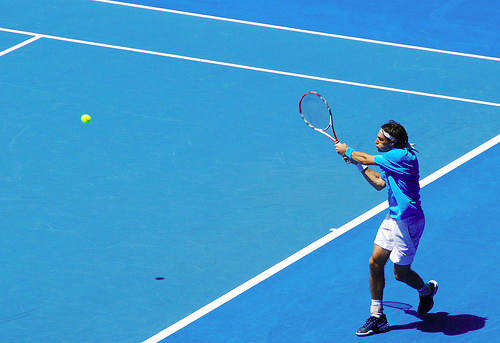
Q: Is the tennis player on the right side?
A: Yes, the player is on the right of the image.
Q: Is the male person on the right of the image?
A: Yes, the player is on the right of the image.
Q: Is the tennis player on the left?
A: No, the player is on the right of the image.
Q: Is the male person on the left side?
A: No, the player is on the right of the image.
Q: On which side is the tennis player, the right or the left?
A: The player is on the right of the image.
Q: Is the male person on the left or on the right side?
A: The player is on the right of the image.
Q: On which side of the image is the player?
A: The player is on the right of the image.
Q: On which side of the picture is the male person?
A: The player is on the right of the image.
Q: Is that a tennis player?
A: Yes, that is a tennis player.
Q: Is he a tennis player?
A: Yes, that is a tennis player.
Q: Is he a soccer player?
A: No, that is a tennis player.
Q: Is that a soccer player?
A: No, that is a tennis player.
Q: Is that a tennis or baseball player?
A: That is a tennis player.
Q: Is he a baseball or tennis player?
A: That is a tennis player.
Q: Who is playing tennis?
A: The player is playing tennis.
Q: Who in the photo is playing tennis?
A: The player is playing tennis.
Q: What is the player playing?
A: The player is playing tennis.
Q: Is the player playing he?
A: Yes, the player is playing tennis.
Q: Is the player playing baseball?
A: No, the player is playing tennis.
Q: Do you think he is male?
A: Yes, the player is male.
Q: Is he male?
A: Yes, the player is male.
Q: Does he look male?
A: Yes, the player is male.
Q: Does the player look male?
A: Yes, the player is male.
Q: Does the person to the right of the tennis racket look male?
A: Yes, the player is male.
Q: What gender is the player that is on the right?
A: The player is male.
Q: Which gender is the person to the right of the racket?
A: The player is male.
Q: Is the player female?
A: No, the player is male.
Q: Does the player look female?
A: No, the player is male.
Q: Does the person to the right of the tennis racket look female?
A: No, the player is male.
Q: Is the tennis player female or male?
A: The player is male.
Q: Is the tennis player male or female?
A: The player is male.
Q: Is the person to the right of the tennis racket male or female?
A: The player is male.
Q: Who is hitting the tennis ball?
A: The player is hitting the tennis ball.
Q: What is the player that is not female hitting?
A: The player is hitting the tennis ball.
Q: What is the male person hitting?
A: The player is hitting the tennis ball.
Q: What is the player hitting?
A: The player is hitting the tennis ball.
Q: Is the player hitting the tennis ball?
A: Yes, the player is hitting the tennis ball.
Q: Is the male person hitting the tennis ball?
A: Yes, the player is hitting the tennis ball.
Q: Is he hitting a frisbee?
A: No, the player is hitting the tennis ball.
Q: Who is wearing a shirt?
A: The player is wearing a shirt.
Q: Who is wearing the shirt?
A: The player is wearing a shirt.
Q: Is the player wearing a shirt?
A: Yes, the player is wearing a shirt.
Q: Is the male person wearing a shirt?
A: Yes, the player is wearing a shirt.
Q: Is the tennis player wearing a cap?
A: No, the player is wearing a shirt.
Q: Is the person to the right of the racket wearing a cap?
A: No, the player is wearing a shirt.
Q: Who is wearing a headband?
A: The player is wearing a headband.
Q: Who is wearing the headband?
A: The player is wearing a headband.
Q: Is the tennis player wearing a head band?
A: Yes, the player is wearing a head band.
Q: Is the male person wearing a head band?
A: Yes, the player is wearing a head band.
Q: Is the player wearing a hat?
A: No, the player is wearing a head band.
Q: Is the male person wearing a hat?
A: No, the player is wearing a head band.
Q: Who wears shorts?
A: The player wears shorts.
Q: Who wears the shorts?
A: The player wears shorts.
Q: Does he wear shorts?
A: Yes, the player wears shorts.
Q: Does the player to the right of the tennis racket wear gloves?
A: No, the player wears shorts.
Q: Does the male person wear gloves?
A: No, the player wears shorts.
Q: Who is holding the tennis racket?
A: The player is holding the tennis racket.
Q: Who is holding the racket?
A: The player is holding the tennis racket.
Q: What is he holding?
A: The player is holding the racket.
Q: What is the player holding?
A: The player is holding the racket.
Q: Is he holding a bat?
A: No, the player is holding the tennis racket.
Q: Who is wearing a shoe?
A: The player is wearing a shoe.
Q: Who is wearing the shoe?
A: The player is wearing a shoe.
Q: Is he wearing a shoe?
A: Yes, the player is wearing a shoe.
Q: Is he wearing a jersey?
A: No, the player is wearing a shoe.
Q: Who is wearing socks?
A: The player is wearing socks.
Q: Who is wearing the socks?
A: The player is wearing socks.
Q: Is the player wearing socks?
A: Yes, the player is wearing socks.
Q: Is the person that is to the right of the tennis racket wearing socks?
A: Yes, the player is wearing socks.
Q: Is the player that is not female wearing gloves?
A: No, the player is wearing socks.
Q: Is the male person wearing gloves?
A: No, the player is wearing socks.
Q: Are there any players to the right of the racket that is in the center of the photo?
A: Yes, there is a player to the right of the racket.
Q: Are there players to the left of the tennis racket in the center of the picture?
A: No, the player is to the right of the racket.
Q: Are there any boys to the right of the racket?
A: No, there is a player to the right of the racket.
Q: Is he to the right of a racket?
A: Yes, the player is to the right of a racket.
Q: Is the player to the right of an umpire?
A: No, the player is to the right of a racket.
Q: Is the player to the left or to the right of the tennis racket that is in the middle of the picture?
A: The player is to the right of the racket.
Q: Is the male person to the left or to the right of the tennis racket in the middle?
A: The player is to the right of the racket.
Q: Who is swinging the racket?
A: The player is swinging the racket.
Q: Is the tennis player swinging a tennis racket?
A: Yes, the player is swinging a tennis racket.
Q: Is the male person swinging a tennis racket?
A: Yes, the player is swinging a tennis racket.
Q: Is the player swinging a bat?
A: No, the player is swinging a tennis racket.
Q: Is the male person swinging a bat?
A: No, the player is swinging a tennis racket.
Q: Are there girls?
A: No, there are no girls.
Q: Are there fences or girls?
A: No, there are no girls or fences.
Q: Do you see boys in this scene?
A: No, there are no boys.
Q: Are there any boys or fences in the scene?
A: No, there are no boys or fences.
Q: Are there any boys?
A: No, there are no boys.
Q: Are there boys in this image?
A: No, there are no boys.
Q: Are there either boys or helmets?
A: No, there are no boys or helmets.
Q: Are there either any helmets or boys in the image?
A: No, there are no boys or helmets.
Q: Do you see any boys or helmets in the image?
A: No, there are no boys or helmets.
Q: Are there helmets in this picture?
A: No, there are no helmets.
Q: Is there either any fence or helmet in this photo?
A: No, there are no helmets or fences.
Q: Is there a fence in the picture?
A: No, there are no fences.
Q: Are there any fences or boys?
A: No, there are no fences or boys.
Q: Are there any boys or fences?
A: No, there are no fences or boys.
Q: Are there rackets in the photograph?
A: Yes, there is a racket.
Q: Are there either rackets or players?
A: Yes, there is a racket.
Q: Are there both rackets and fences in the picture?
A: No, there is a racket but no fences.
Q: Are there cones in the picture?
A: No, there are no cones.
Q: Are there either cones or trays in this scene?
A: No, there are no cones or trays.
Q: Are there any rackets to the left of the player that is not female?
A: Yes, there is a racket to the left of the player.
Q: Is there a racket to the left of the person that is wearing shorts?
A: Yes, there is a racket to the left of the player.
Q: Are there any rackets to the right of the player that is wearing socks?
A: No, the racket is to the left of the player.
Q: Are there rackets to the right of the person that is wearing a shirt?
A: No, the racket is to the left of the player.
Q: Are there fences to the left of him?
A: No, there is a racket to the left of the player.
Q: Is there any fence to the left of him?
A: No, there is a racket to the left of the player.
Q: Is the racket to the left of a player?
A: Yes, the racket is to the left of a player.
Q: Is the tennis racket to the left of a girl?
A: No, the tennis racket is to the left of a player.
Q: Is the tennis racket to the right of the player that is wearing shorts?
A: No, the tennis racket is to the left of the player.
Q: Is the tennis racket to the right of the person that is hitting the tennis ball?
A: No, the tennis racket is to the left of the player.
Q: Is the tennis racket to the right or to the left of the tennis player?
A: The tennis racket is to the left of the player.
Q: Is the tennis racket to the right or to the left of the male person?
A: The tennis racket is to the left of the player.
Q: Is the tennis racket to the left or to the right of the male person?
A: The tennis racket is to the left of the player.